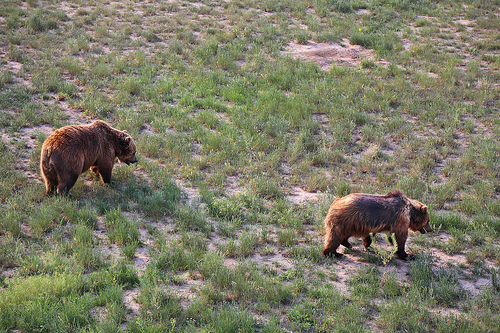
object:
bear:
[41, 120, 138, 197]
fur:
[346, 205, 362, 217]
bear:
[323, 191, 434, 262]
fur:
[357, 190, 406, 224]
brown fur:
[82, 132, 100, 149]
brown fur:
[52, 132, 68, 147]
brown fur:
[67, 141, 84, 155]